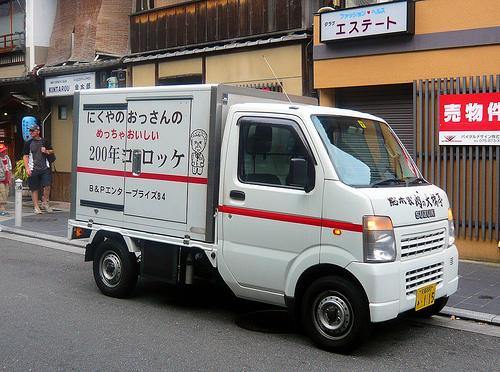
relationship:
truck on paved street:
[67, 84, 459, 352] [0, 155, 500, 372]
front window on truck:
[237, 120, 317, 191] [42, 67, 465, 369]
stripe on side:
[73, 157, 365, 239] [214, 70, 385, 353]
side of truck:
[214, 70, 385, 353] [42, 67, 465, 369]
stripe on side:
[73, 157, 365, 239] [214, 102, 376, 354]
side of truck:
[214, 102, 376, 354] [67, 84, 459, 352]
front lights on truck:
[363, 216, 393, 231] [67, 84, 459, 352]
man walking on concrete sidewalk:
[22, 124, 57, 214] [0, 190, 500, 327]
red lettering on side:
[96, 128, 159, 140] [214, 102, 376, 354]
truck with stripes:
[67, 84, 459, 352] [60, 155, 216, 199]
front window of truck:
[241, 120, 322, 190] [59, 49, 467, 354]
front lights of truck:
[359, 218, 468, 254] [67, 84, 459, 352]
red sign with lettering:
[434, 92, 492, 141] [441, 95, 484, 131]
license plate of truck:
[410, 282, 443, 314] [67, 84, 459, 352]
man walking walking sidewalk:
[20, 123, 64, 218] [9, 180, 476, 336]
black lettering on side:
[86, 109, 188, 127] [214, 102, 376, 354]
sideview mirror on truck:
[285, 153, 314, 188] [67, 84, 459, 352]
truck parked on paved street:
[67, 84, 459, 352] [0, 155, 500, 372]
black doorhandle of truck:
[225, 190, 249, 203] [67, 84, 459, 352]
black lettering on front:
[86, 109, 183, 125] [207, 75, 470, 342]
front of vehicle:
[207, 75, 470, 342] [57, 48, 482, 350]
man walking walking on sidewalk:
[22, 124, 57, 214] [0, 164, 485, 370]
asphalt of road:
[5, 220, 412, 366] [1, 227, 497, 372]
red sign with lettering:
[434, 92, 492, 141] [434, 96, 460, 126]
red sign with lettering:
[434, 92, 492, 141] [463, 100, 484, 123]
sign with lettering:
[321, 3, 407, 40] [327, 21, 345, 37]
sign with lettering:
[321, 3, 407, 40] [344, 17, 359, 33]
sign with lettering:
[321, 3, 407, 40] [356, 17, 374, 38]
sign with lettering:
[321, 3, 407, 40] [374, 13, 397, 35]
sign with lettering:
[321, 3, 407, 40] [339, 10, 399, 19]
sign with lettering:
[321, 3, 407, 40] [332, 16, 403, 43]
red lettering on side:
[97, 127, 164, 143] [56, 73, 218, 254]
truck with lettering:
[67, 84, 459, 352] [68, 95, 187, 204]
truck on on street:
[67, 84, 459, 352] [1, 232, 263, 370]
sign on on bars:
[321, 3, 407, 40] [49, 0, 313, 202]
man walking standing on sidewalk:
[22, 124, 57, 214] [5, 202, 498, 332]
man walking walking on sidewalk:
[22, 124, 57, 214] [9, 180, 476, 336]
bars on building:
[119, 2, 314, 38] [248, 7, 484, 282]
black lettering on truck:
[86, 109, 183, 125] [67, 84, 459, 352]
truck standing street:
[57, 78, 460, 342] [2, 232, 483, 370]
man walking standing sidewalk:
[22, 124, 57, 214] [19, 190, 483, 330]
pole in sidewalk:
[8, 170, 26, 228] [25, 204, 484, 318]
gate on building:
[407, 68, 483, 239] [313, 10, 484, 263]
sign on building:
[324, 11, 413, 43] [313, 10, 484, 263]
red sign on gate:
[434, 92, 500, 146] [395, 67, 484, 234]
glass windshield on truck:
[306, 112, 426, 187] [67, 84, 459, 352]